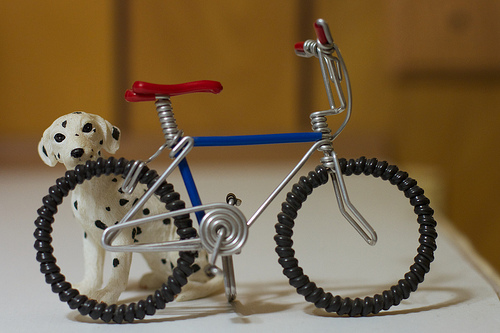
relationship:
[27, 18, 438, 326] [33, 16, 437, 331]
bicycle made with paper clips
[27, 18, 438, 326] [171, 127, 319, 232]
bicycle has blue body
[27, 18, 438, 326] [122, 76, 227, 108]
bicycle has seat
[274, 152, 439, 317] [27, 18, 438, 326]
tire on bicycle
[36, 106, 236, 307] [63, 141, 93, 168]
dog has nose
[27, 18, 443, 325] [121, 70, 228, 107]
bicycle has seat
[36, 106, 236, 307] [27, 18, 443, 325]
dog stands behind bicycle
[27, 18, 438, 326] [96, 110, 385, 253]
bicycle has frame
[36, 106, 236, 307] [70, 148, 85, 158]
dog has dog nose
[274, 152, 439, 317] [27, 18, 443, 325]
tire on bicycle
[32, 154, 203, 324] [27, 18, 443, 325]
tire on bicycle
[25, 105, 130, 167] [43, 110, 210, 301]
face of dog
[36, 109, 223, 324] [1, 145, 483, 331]
dog on table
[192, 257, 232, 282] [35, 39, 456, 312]
pedal on bike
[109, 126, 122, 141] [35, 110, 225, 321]
spot on dog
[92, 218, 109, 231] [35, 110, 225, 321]
spot on dog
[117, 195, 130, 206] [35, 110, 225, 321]
spot on dog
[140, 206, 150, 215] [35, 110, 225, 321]
spot on dog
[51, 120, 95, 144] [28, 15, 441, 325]
eyes on dog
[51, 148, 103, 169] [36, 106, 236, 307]
black nose on dog